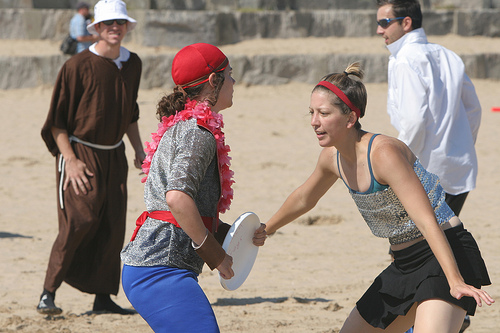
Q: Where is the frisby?
A: In the woman on the left's hands.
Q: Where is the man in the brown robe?
A: On the far left.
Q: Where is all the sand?
A: On the ground.